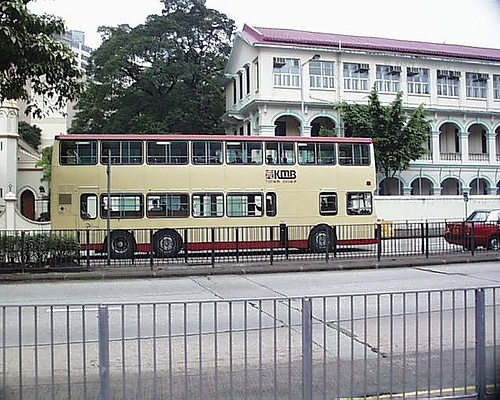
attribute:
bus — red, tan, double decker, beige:
[48, 135, 379, 267]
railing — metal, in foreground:
[0, 282, 497, 399]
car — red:
[444, 210, 499, 248]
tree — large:
[67, 1, 239, 133]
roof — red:
[235, 20, 498, 68]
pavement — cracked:
[0, 257, 498, 400]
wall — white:
[373, 194, 498, 230]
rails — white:
[407, 81, 432, 95]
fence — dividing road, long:
[1, 216, 496, 275]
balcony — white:
[466, 83, 488, 99]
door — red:
[16, 191, 38, 221]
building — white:
[218, 18, 499, 197]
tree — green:
[328, 82, 437, 198]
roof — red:
[54, 132, 375, 146]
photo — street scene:
[1, 1, 496, 397]